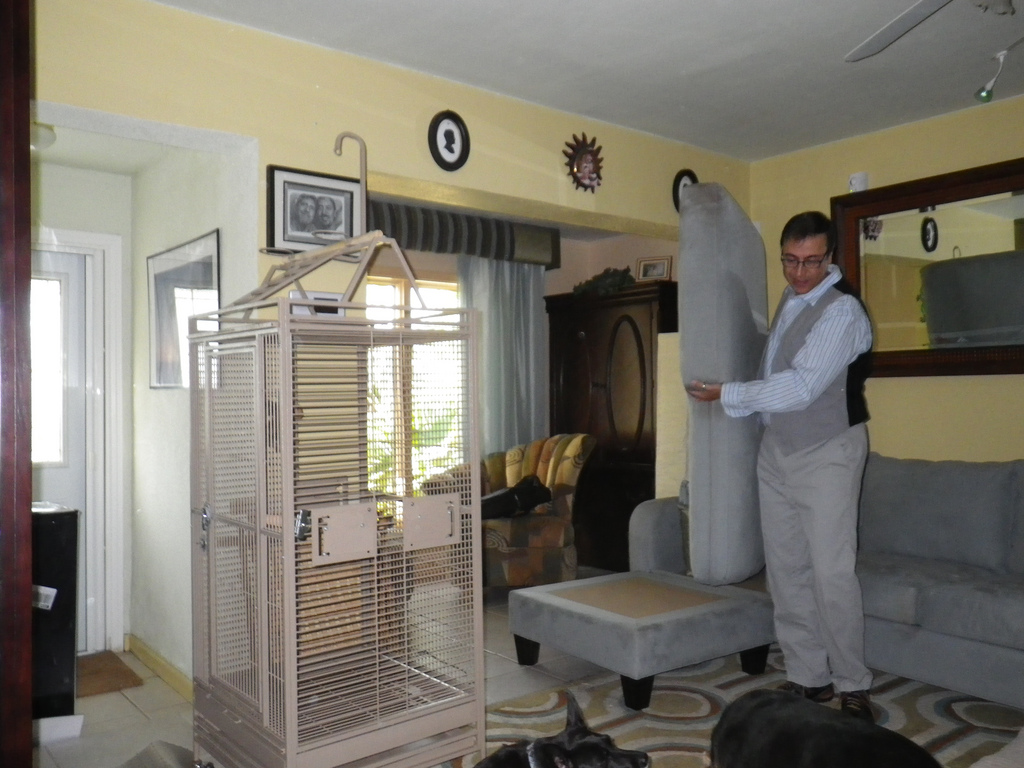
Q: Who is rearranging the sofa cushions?
A: A well dressed man.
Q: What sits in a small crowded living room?
A: A large empty cage.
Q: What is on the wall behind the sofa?
A: A large mirror.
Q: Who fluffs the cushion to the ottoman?
A: A man.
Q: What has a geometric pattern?
A: A rug on the floor.